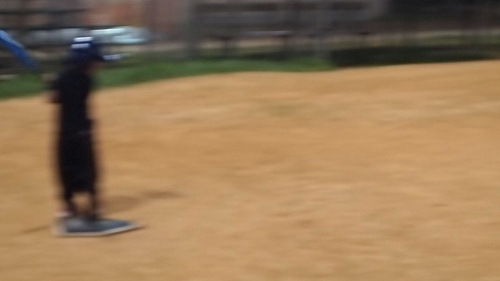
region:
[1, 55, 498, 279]
dirt under player is light brown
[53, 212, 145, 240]
home plate is black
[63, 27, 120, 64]
player has on blue hat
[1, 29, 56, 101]
person holding blue baseball bat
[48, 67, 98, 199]
player is wearing black gear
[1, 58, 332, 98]
dark green grass by ball field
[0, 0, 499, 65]
black chain link fence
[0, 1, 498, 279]
the shot is blurry and out of focus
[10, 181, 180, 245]
person casting shadow on dirt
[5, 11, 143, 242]
young kid getting ready to swing a bat.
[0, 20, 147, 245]
young kid getting ready to swing a bat.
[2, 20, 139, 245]
young kid getting ready to swing a bat.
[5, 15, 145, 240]
young kid getting ready to swing a bat.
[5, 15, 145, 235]
young kid getting ready to swing a bat.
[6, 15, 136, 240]
young kid getting ready to swing a bat.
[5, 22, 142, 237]
young kid getting ready to swing a bat.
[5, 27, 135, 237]
young kid getting ready to swing a bat.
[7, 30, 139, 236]
young kid getting ready to swing a bat.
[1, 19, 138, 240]
batter is blurred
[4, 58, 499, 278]
brown dirt on a baseball field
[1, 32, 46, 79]
blue blurry baseball bat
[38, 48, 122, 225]
batter wears black clothing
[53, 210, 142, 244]
base plate is blue and white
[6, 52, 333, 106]
green grass on a baseball field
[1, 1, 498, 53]
fencing alongside a baseball field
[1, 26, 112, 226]
batter is swinging a baseball bat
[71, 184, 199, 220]
shadow of a batter on the ground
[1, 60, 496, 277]
a baseball field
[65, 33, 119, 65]
a blue helmet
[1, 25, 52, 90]
a blue bat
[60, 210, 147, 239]
a home plate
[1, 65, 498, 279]
the red dirt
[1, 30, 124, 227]
a boy on field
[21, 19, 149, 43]
cars in distance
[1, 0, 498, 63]
a fence around field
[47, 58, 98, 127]
a black shirt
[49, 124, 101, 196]
a pair of shorts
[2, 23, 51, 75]
bat in the air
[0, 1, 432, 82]
fence on the field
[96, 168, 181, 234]
shadow of the person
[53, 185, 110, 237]
legs of the person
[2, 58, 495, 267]
dirt on the ground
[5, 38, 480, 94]
grass around the dirt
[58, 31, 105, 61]
head of the person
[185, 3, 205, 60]
pole of the fence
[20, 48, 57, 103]
handle of the bat